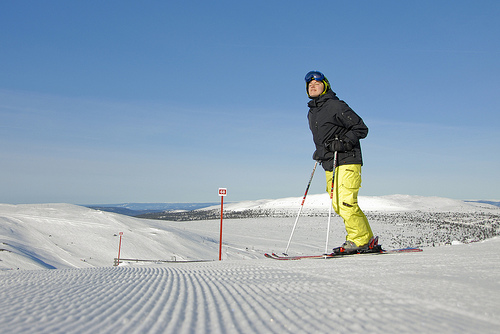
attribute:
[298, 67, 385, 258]
man — skiiing, woman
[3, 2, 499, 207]
sky — blue, `blue, clear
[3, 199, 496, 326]
snow — fresh, fluffy, white, hilly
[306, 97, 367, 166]
jacket — black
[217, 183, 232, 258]
sign — red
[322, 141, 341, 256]
ski pole — red, white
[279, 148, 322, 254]
ski pole — red, white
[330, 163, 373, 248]
pants — yellow